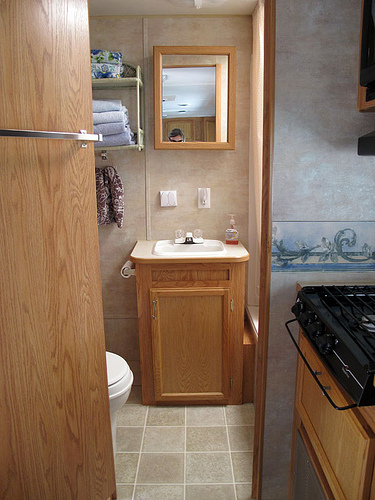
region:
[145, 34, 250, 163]
wooden framed bathroom mirror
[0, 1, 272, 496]
a bathroom with an open door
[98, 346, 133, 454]
a white toilet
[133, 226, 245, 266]
a small sink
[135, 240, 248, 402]
cabinet beneath sink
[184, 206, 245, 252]
pump bottle beside sink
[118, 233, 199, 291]
toilet paper roll near sink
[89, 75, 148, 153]
folded towels on shelf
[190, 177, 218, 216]
nightlight plugged into an outlet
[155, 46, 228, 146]
top of woman's head and doorway reflected in mirror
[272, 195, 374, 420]
black stove top near wall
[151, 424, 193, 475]
the floor is tiled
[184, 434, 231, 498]
the floor is tiled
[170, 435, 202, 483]
the floor is tiled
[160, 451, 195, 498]
the floor is tiled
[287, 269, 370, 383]
Stove is black color.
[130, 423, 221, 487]
Floor is brown color.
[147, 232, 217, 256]
sink is white color.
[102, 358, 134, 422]
Toilet is white color.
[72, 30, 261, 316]
Door is open.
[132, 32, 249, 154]
Mirror is attached to the wall.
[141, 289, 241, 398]
Cupboards are brown color.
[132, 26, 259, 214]
Wall is brown color.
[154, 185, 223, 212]
Switch is attached to the wall.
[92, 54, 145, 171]
Clothes are folded and arranged in rack.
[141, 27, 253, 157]
mirror on the wall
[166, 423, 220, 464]
floor below the cabinet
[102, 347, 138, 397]
toilet next to sink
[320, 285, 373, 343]
stove above ground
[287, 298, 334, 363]
knobs on the stove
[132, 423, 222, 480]
floor with square tiles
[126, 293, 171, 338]
handle of the cabinet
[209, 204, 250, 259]
soap next to the sink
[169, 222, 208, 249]
faucet of the sink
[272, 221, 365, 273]
design on the wall